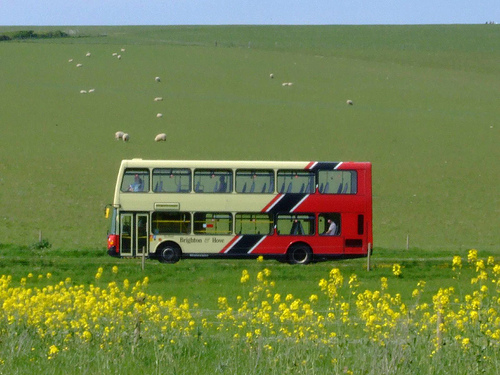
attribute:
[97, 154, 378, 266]
bus — double decker, traveling, partially tan, partially red, red, blue, white,, facing left, green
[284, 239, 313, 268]
back wheel — black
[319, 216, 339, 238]
man — sitting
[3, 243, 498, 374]
flowers — yellow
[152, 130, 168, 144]
sheep — grazing, white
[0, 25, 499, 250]
field — grass, green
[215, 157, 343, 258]
stripe — diagonal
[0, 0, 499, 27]
sky — blue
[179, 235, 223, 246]
letters — blue